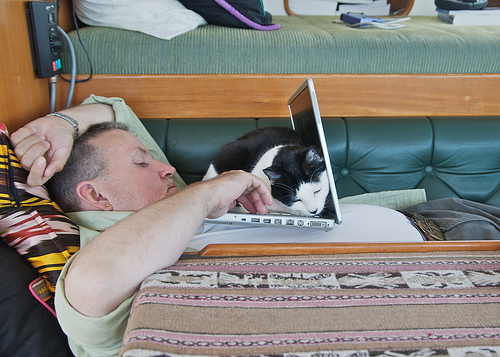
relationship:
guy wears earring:
[9, 92, 500, 357] [96, 190, 118, 215]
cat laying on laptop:
[200, 125, 335, 220] [194, 62, 347, 227]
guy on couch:
[9, 92, 500, 357] [3, 119, 496, 356]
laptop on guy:
[199, 76, 344, 230] [9, 92, 500, 357]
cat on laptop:
[200, 125, 335, 220] [199, 76, 344, 230]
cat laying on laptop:
[200, 125, 335, 220] [199, 76, 344, 230]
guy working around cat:
[9, 92, 500, 357] [200, 125, 335, 220]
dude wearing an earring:
[10, 92, 235, 319] [100, 201, 112, 210]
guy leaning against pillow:
[76, 122, 484, 326] [2, 120, 51, 266]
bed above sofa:
[3, 0, 499, 96] [0, 108, 499, 352]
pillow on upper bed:
[71, 0, 206, 47] [57, 14, 499, 121]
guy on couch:
[9, 92, 500, 357] [107, 117, 499, 205]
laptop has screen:
[199, 76, 344, 230] [286, 77, 342, 222]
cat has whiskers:
[200, 125, 335, 220] [270, 181, 298, 202]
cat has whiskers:
[200, 125, 335, 220] [309, 163, 329, 184]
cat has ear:
[200, 125, 335, 220] [259, 162, 280, 183]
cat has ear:
[200, 125, 335, 220] [306, 141, 316, 161]